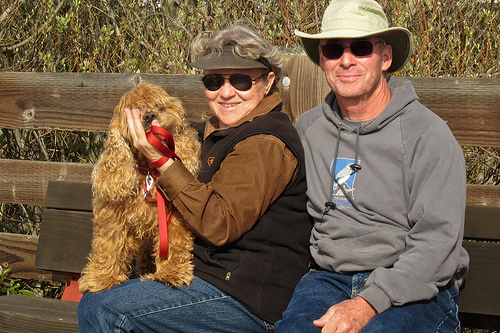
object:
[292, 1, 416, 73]
hat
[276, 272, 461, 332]
blue jeans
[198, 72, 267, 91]
sunglasses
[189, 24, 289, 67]
hair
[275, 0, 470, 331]
man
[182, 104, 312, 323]
vest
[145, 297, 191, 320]
blue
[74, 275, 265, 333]
jeans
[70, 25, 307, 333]
woman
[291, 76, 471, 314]
gray shirt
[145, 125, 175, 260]
red leash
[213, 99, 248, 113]
smile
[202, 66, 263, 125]
face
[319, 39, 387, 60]
sunglasses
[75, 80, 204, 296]
dog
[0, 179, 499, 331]
bench